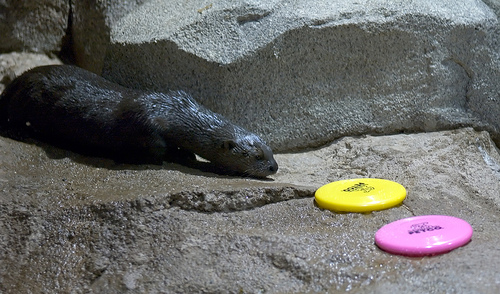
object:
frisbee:
[313, 177, 408, 213]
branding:
[407, 221, 443, 234]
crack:
[447, 56, 475, 114]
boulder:
[69, 1, 499, 153]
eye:
[255, 154, 266, 161]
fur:
[60, 77, 110, 125]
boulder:
[0, 0, 70, 54]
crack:
[93, 180, 315, 219]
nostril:
[267, 164, 274, 171]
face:
[237, 144, 279, 177]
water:
[0, 137, 314, 293]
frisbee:
[373, 213, 472, 256]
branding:
[341, 182, 375, 193]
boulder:
[0, 126, 499, 292]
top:
[374, 214, 472, 248]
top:
[315, 177, 406, 206]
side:
[220, 153, 254, 172]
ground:
[5, 131, 496, 287]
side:
[0, 72, 161, 163]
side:
[224, 14, 499, 152]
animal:
[0, 64, 279, 178]